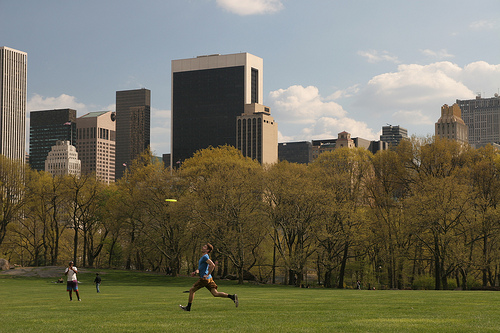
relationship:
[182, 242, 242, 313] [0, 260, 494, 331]
man in park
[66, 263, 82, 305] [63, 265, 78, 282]
man wearing shirt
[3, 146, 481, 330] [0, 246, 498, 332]
city park has green grass field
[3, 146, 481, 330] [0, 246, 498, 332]
city park has people playing on grass field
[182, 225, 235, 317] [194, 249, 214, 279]
man in shirt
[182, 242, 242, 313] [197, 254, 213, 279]
man wearing a shirt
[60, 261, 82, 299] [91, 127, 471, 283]
man present at park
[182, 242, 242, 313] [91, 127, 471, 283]
man present at park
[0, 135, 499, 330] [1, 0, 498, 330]
city park within city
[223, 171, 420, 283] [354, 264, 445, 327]
trees at park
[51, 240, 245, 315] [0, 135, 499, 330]
people shown in city park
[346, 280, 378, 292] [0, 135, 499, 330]
people shown in city park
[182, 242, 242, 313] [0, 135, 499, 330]
man at city park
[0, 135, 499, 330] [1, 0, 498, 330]
city park in city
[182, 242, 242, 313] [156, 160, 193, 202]
man playing frisbee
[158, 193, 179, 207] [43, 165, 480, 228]
frisbee flying at tree level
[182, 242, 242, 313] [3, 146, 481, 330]
man in a city park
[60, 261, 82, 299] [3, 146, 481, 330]
man in a city park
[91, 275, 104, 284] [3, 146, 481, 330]
jacket in a city park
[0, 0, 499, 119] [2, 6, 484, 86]
cloud in a sky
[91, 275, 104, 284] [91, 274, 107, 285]
jacket wearing jacket